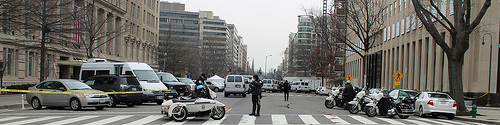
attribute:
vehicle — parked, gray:
[23, 77, 112, 112]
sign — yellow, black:
[390, 65, 407, 83]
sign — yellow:
[342, 72, 353, 83]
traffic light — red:
[217, 62, 242, 83]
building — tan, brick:
[337, 1, 499, 111]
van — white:
[221, 67, 261, 113]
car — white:
[411, 89, 465, 119]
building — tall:
[158, 7, 199, 79]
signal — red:
[226, 64, 235, 75]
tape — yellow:
[1, 87, 170, 98]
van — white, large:
[82, 60, 166, 109]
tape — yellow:
[1, 89, 174, 96]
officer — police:
[244, 69, 262, 118]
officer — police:
[195, 72, 206, 90]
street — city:
[0, 87, 499, 124]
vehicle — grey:
[77, 70, 143, 110]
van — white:
[227, 76, 255, 97]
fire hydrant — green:
[468, 98, 479, 123]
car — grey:
[418, 92, 461, 114]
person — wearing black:
[281, 77, 291, 102]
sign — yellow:
[389, 68, 409, 90]